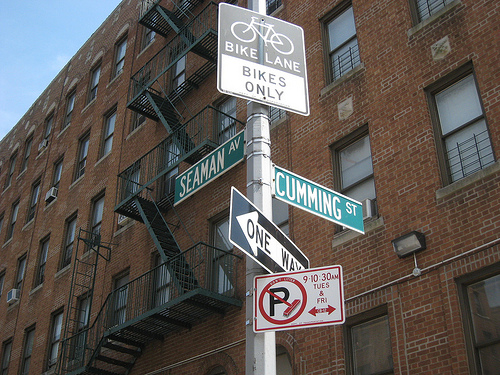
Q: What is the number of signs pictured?
A: 5.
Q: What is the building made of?
A: Brick.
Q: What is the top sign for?
A: Bike Lane.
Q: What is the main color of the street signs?
A: Green and white.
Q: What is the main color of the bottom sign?
A: Red and white.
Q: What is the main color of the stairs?
A: Black.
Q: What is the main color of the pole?
A: Gray.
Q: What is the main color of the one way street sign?
A: Black and white.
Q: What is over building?
A: Blue sky.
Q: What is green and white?
A: Signs.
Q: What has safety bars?
A: Window.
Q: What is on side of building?
A: Fire escape.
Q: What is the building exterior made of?
A: Brick.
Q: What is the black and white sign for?
A: Bikes only.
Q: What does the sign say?
A: No parking.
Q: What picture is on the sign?
A: Bike.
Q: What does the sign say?
A: One way.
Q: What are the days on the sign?
A: Tuesday and Friday.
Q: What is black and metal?
A: Stair cases.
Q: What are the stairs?
A: Fire escape.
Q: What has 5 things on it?
A: Post.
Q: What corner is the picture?
A: Seaman ave and Cumming St.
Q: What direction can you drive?
A: Left.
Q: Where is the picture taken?
A: On the corner.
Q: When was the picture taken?
A: During the day.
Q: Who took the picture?
A: Someone who thought seaman and cumming was funny.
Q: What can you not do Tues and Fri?
A: Park.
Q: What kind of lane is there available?
A: Bike lanes.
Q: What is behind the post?
A: Apartment buildings.